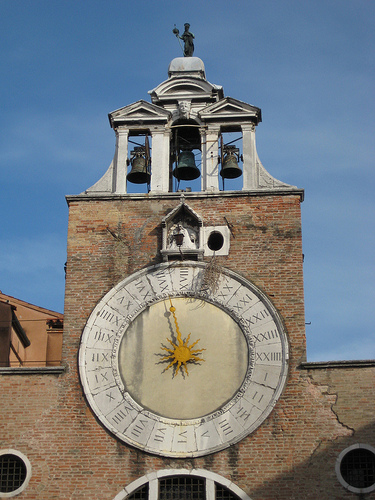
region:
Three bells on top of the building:
[113, 106, 286, 191]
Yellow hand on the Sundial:
[120, 245, 206, 374]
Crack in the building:
[293, 334, 368, 446]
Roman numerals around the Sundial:
[95, 260, 283, 449]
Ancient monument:
[28, 56, 282, 487]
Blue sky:
[11, 11, 103, 176]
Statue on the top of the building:
[154, 1, 253, 93]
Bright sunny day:
[15, 10, 326, 390]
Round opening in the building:
[0, 439, 38, 496]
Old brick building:
[77, 204, 134, 295]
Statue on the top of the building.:
[139, 9, 203, 55]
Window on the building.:
[138, 466, 260, 498]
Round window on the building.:
[306, 439, 372, 492]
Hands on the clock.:
[134, 280, 254, 418]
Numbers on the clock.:
[58, 345, 210, 480]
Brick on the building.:
[65, 408, 151, 476]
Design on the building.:
[122, 192, 258, 266]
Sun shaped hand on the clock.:
[154, 288, 234, 389]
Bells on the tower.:
[106, 86, 352, 259]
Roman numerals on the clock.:
[79, 255, 258, 328]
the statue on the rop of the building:
[167, 19, 201, 55]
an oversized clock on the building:
[77, 265, 291, 455]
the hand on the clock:
[152, 295, 201, 379]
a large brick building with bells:
[7, 58, 373, 495]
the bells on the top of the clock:
[125, 136, 246, 186]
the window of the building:
[334, 439, 372, 496]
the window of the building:
[99, 463, 259, 497]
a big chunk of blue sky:
[224, 4, 367, 349]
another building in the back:
[0, 298, 69, 368]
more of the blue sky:
[13, 17, 145, 182]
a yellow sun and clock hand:
[156, 294, 204, 379]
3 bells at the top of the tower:
[126, 126, 244, 187]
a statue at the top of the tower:
[171, 20, 197, 57]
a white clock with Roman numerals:
[77, 260, 290, 458]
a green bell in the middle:
[171, 142, 199, 181]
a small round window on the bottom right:
[333, 441, 374, 492]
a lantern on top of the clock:
[171, 222, 187, 262]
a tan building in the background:
[1, 289, 63, 366]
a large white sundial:
[76, 258, 291, 456]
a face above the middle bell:
[174, 98, 192, 119]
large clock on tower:
[77, 260, 291, 459]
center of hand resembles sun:
[155, 332, 206, 377]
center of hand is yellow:
[154, 332, 205, 378]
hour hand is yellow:
[165, 292, 180, 340]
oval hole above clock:
[204, 227, 219, 244]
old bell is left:
[123, 152, 143, 176]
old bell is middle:
[168, 147, 194, 177]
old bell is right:
[217, 150, 236, 174]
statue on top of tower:
[169, 19, 192, 50]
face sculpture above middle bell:
[176, 99, 186, 111]